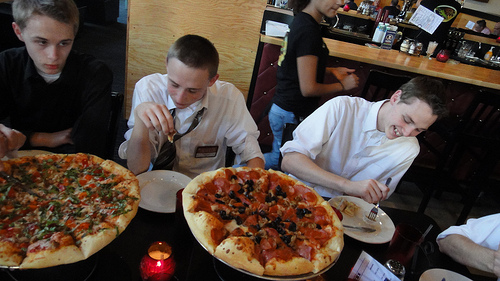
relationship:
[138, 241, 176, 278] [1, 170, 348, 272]
candle holder on table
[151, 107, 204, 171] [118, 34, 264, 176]
tie on boy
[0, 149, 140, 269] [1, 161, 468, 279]
pizza on top of table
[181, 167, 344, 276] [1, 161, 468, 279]
pizza on top of table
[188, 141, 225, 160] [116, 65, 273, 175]
name tag on shirt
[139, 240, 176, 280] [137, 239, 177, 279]
candle in holder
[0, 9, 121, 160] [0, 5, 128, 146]
boy sitting in front of area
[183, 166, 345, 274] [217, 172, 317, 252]
pizza with black olives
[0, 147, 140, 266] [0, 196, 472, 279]
pizza on table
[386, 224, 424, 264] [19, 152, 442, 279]
glass on table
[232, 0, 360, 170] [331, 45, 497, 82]
person on counter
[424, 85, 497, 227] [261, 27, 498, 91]
stool in front of counter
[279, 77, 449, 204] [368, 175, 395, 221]
boy holding fork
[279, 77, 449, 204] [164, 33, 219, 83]
boy with hair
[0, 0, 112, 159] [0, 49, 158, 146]
boy wearing tee shirt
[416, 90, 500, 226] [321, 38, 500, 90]
stool at counter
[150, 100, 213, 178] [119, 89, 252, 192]
tie on shirt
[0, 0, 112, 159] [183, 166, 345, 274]
boy eating pizza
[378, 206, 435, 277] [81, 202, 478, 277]
glass on table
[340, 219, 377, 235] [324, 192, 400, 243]
utensil on plate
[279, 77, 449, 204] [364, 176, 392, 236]
boy holding fork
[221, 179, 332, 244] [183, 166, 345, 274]
olives on pizza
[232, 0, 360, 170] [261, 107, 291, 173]
person wearing jeans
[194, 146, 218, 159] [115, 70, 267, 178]
name tag on mans shirt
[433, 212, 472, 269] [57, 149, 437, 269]
elbow on edge  of table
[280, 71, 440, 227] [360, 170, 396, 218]
boy using fork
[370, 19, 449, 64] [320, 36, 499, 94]
condiments on counter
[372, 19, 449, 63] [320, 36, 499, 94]
toothpicks on counter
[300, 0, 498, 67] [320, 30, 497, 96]
shelve on side of counter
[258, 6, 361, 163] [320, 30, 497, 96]
person on side of counter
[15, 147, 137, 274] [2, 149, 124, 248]
pie with toppings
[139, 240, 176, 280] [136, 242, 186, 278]
candle in red glass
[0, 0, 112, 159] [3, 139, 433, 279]
boy sitting at table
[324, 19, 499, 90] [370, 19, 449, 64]
counter with condiments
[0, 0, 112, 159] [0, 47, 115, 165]
boy wearing shirt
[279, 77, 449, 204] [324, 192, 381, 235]
boy eating food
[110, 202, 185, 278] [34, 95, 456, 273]
candle on table